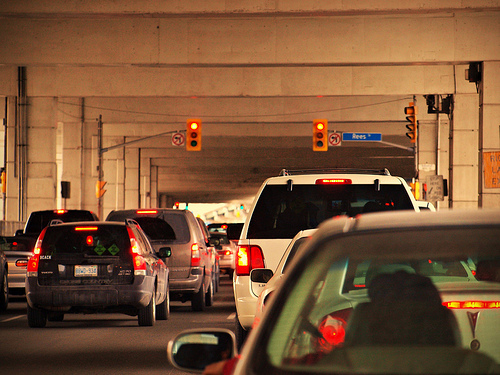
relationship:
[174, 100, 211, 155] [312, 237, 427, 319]
light on car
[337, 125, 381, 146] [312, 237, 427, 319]
sign in car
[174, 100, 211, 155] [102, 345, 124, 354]
light on street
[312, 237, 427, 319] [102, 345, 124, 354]
car on street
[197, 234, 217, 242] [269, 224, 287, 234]
hand out window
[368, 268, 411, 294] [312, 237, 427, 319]
driver in car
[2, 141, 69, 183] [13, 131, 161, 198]
pillar of tunnel